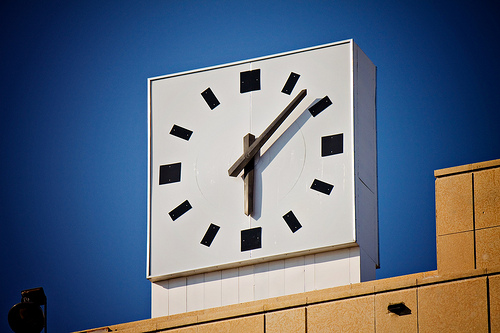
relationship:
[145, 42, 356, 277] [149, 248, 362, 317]
clock has clock base